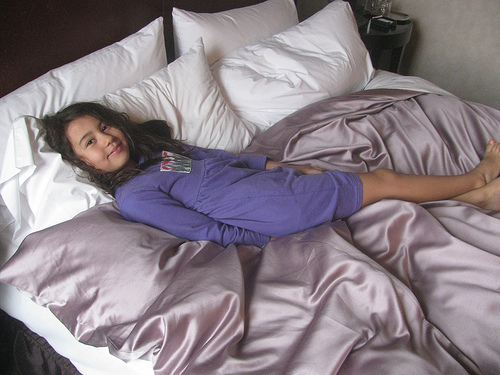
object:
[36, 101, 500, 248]
girl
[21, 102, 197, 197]
hair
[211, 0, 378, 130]
pillow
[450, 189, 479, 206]
legs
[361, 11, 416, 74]
stand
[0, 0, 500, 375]
bed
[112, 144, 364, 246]
clothes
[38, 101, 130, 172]
head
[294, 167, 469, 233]
leg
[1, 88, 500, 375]
duvet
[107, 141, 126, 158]
smile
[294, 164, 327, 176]
hand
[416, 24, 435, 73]
shadow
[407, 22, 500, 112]
wall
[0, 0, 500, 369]
bedding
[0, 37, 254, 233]
pillow